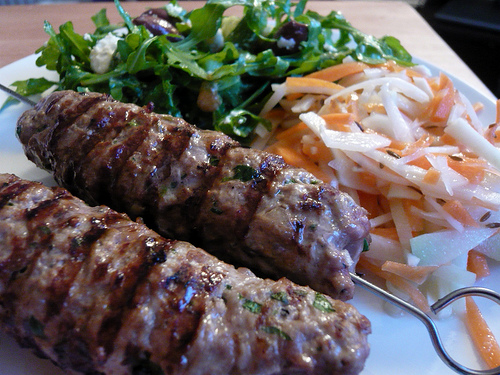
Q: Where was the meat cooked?
A: On a grill.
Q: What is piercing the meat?
A: Skewer.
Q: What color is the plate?
A: White.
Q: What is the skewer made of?
A: Metal.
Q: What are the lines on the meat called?
A: Grill marks.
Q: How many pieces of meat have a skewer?
A: 1.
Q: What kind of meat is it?
A: Sausage.